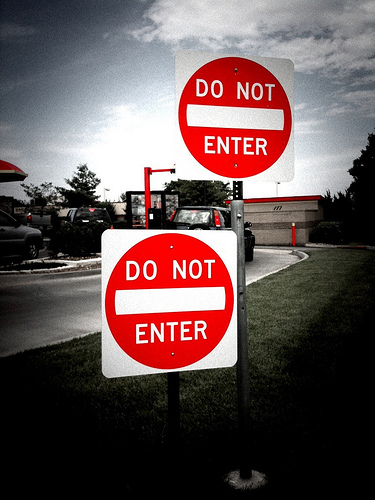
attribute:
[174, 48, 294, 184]
sign — white, red, tall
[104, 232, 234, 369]
circle — red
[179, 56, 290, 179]
circle — red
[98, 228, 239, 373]
sign — red, white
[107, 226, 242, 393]
traffic sign — square, white, red, metal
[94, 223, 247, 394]
traffic sign — square, white, red, metal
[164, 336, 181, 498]
sign post — metal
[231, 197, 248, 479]
sign post — metal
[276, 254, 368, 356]
grass — large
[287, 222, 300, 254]
pole — red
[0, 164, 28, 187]
umbrella — red, white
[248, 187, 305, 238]
building — small, gray, white, red, brick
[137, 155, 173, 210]
pole — red, metal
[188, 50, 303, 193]
sign — white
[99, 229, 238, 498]
sign — short, red, white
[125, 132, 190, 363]
light — yellow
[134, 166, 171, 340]
pole — yellow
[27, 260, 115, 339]
road — small, icy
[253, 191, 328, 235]
building — small, gray,  concrete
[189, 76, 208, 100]
letter —  white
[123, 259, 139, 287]
letter —  white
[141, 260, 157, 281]
letter —  white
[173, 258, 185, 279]
letter —  white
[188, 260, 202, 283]
letter —  white